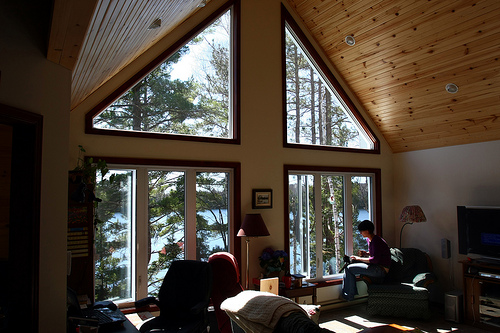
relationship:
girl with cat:
[349, 223, 387, 258] [337, 255, 364, 271]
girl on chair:
[349, 223, 387, 258] [369, 242, 437, 321]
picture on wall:
[249, 182, 277, 214] [232, 147, 300, 286]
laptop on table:
[65, 287, 126, 328] [87, 295, 138, 331]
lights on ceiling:
[331, 26, 478, 102] [329, 19, 465, 152]